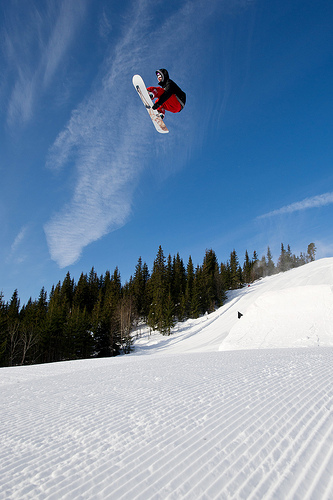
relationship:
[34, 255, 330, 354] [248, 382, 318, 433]
hill in snow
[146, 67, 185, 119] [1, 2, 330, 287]
man in sky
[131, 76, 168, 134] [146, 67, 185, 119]
board under man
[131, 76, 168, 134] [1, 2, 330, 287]
board in sky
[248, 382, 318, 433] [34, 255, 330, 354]
snow on hill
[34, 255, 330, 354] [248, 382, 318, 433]
hill of snow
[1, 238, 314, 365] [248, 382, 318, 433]
trees and snow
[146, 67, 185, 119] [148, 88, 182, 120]
man with red pants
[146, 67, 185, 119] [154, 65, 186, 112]
man in jacket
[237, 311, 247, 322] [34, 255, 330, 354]
flag on hill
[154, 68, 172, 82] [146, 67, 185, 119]
head of man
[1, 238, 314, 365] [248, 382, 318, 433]
trees on snow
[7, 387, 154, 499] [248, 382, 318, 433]
tracks on snow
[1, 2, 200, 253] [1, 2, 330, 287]
clouds in sky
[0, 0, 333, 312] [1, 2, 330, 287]
clouds in sky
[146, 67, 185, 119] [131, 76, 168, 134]
man on board